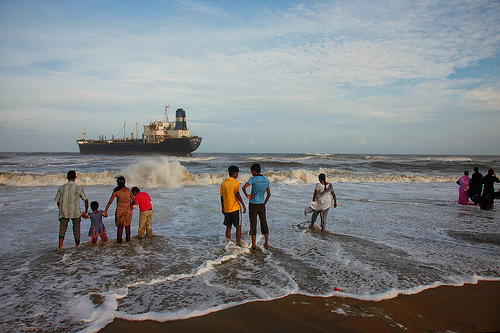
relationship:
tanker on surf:
[71, 100, 204, 164] [47, 142, 310, 195]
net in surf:
[294, 214, 316, 231] [0, 164, 499, 322]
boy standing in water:
[239, 157, 277, 264] [12, 157, 480, 297]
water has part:
[160, 252, 232, 303] [164, 214, 184, 237]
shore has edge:
[29, 216, 476, 331] [357, 279, 433, 304]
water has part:
[0, 150, 499, 332] [175, 199, 198, 246]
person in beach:
[51, 167, 89, 252] [13, 197, 489, 331]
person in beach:
[103, 171, 140, 243] [6, 233, 498, 331]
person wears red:
[127, 184, 159, 244] [133, 186, 154, 211]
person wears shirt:
[219, 163, 245, 244] [221, 177, 240, 217]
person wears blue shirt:
[242, 163, 271, 253] [246, 173, 271, 204]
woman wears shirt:
[302, 172, 339, 233] [308, 180, 334, 212]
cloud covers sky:
[350, 96, 447, 128] [4, 8, 498, 157]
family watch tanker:
[44, 164, 162, 247] [70, 109, 205, 160]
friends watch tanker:
[218, 151, 278, 256] [69, 104, 226, 170]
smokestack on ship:
[175, 107, 185, 129] [76, 101, 201, 155]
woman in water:
[107, 176, 131, 239] [71, 162, 196, 192]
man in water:
[49, 162, 89, 252] [19, 228, 126, 295]